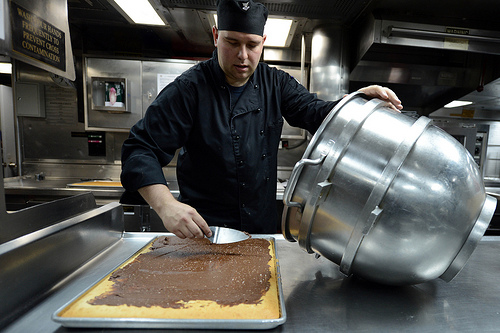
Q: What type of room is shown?
A: It is a kitchen.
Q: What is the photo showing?
A: It is showing a kitchen.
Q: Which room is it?
A: It is a kitchen.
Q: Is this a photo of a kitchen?
A: Yes, it is showing a kitchen.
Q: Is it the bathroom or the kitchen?
A: It is the kitchen.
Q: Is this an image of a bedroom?
A: No, the picture is showing a kitchen.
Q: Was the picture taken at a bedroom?
A: No, the picture was taken in a kitchen.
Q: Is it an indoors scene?
A: Yes, it is indoors.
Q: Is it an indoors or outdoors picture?
A: It is indoors.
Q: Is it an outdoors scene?
A: No, it is indoors.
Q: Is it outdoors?
A: No, it is indoors.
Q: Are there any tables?
A: Yes, there is a table.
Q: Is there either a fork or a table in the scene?
A: Yes, there is a table.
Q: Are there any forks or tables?
A: Yes, there is a table.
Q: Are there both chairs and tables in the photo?
A: No, there is a table but no chairs.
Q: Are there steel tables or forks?
A: Yes, there is a steel table.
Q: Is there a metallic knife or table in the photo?
A: Yes, there is a metal table.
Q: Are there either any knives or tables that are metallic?
A: Yes, the table is metallic.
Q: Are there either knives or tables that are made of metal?
A: Yes, the table is made of metal.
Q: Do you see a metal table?
A: Yes, there is a metal table.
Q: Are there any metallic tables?
A: Yes, there is a metal table.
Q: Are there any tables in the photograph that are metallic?
A: Yes, there is a table that is metallic.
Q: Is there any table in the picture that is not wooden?
A: Yes, there is a metallic table.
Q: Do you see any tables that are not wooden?
A: Yes, there is a metallic table.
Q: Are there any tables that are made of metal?
A: Yes, there is a table that is made of metal.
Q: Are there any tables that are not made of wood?
A: Yes, there is a table that is made of metal.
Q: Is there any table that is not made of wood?
A: Yes, there is a table that is made of metal.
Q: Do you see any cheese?
A: No, there is no cheese.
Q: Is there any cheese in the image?
A: No, there is no cheese.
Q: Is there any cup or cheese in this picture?
A: No, there are no cheese or cups.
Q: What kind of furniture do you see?
A: The furniture is a table.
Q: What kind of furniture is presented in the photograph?
A: The furniture is a table.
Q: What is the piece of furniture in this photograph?
A: The piece of furniture is a table.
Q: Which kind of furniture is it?
A: The piece of furniture is a table.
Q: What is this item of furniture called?
A: This is a table.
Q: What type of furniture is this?
A: This is a table.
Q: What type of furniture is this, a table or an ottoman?
A: This is a table.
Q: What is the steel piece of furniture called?
A: The piece of furniture is a table.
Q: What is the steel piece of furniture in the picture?
A: The piece of furniture is a table.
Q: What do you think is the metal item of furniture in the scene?
A: The piece of furniture is a table.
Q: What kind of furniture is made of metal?
A: The furniture is a table.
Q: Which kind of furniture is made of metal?
A: The furniture is a table.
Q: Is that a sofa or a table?
A: That is a table.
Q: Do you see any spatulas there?
A: Yes, there is a spatula.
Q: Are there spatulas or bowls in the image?
A: Yes, there is a spatula.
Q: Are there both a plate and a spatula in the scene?
A: No, there is a spatula but no plates.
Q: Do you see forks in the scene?
A: No, there are no forks.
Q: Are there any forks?
A: No, there are no forks.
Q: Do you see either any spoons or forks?
A: No, there are no forks or spoons.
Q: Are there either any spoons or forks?
A: No, there are no forks or spoons.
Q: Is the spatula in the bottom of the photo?
A: Yes, the spatula is in the bottom of the image.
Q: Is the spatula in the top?
A: No, the spatula is in the bottom of the image.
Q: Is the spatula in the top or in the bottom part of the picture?
A: The spatula is in the bottom of the image.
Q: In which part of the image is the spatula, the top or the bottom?
A: The spatula is in the bottom of the image.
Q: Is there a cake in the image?
A: Yes, there is a cake.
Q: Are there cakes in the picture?
A: Yes, there is a cake.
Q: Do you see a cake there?
A: Yes, there is a cake.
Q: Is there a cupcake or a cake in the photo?
A: Yes, there is a cake.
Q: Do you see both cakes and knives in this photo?
A: No, there is a cake but no knives.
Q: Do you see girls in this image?
A: No, there are no girls.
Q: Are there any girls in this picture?
A: No, there are no girls.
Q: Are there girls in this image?
A: No, there are no girls.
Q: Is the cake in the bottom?
A: Yes, the cake is in the bottom of the image.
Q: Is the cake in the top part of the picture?
A: No, the cake is in the bottom of the image.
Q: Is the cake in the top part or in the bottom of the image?
A: The cake is in the bottom of the image.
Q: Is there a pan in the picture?
A: Yes, there is a pan.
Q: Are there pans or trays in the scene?
A: Yes, there is a pan.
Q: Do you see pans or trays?
A: Yes, there is a pan.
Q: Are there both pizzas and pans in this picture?
A: No, there is a pan but no pizzas.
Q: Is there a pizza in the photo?
A: No, there are no pizzas.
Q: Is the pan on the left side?
A: Yes, the pan is on the left of the image.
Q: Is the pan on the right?
A: No, the pan is on the left of the image.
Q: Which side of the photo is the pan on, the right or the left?
A: The pan is on the left of the image.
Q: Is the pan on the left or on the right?
A: The pan is on the left of the image.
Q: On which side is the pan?
A: The pan is on the left of the image.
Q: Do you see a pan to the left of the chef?
A: Yes, there is a pan to the left of the chef.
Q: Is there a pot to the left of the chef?
A: No, there is a pan to the left of the chef.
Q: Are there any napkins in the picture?
A: No, there are no napkins.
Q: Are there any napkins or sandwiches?
A: No, there are no napkins or sandwiches.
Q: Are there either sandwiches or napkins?
A: No, there are no napkins or sandwiches.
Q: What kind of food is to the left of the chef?
A: The food is a dessert.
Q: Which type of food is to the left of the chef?
A: The food is a dessert.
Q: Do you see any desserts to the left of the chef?
A: Yes, there is a dessert to the left of the chef.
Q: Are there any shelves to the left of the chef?
A: No, there is a dessert to the left of the chef.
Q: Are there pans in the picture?
A: Yes, there is a pan.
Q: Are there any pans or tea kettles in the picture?
A: Yes, there is a pan.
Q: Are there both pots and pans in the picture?
A: No, there is a pan but no pots.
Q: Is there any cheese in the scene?
A: No, there is no cheese.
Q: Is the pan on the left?
A: Yes, the pan is on the left of the image.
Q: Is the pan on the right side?
A: No, the pan is on the left of the image.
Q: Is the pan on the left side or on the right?
A: The pan is on the left of the image.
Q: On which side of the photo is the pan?
A: The pan is on the left of the image.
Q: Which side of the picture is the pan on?
A: The pan is on the left of the image.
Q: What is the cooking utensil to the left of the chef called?
A: The cooking utensil is a pan.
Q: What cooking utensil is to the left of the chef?
A: The cooking utensil is a pan.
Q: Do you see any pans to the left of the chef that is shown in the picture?
A: Yes, there is a pan to the left of the chef.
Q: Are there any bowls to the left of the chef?
A: No, there is a pan to the left of the chef.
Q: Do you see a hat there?
A: Yes, there is a hat.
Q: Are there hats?
A: Yes, there is a hat.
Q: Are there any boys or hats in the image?
A: Yes, there is a hat.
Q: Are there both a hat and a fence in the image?
A: No, there is a hat but no fences.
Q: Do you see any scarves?
A: No, there are no scarves.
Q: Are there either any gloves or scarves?
A: No, there are no scarves or gloves.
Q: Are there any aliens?
A: No, there are no aliens.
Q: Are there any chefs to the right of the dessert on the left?
A: Yes, there is a chef to the right of the dessert.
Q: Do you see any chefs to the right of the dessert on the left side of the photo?
A: Yes, there is a chef to the right of the dessert.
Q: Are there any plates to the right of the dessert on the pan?
A: No, there is a chef to the right of the dessert.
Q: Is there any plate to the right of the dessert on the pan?
A: No, there is a chef to the right of the dessert.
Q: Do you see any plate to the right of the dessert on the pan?
A: No, there is a chef to the right of the dessert.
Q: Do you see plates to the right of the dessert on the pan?
A: No, there is a chef to the right of the dessert.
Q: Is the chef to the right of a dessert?
A: Yes, the chef is to the right of a dessert.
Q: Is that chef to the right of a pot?
A: No, the chef is to the right of a dessert.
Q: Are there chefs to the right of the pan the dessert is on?
A: Yes, there is a chef to the right of the pan.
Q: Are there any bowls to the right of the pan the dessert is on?
A: No, there is a chef to the right of the pan.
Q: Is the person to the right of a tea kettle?
A: No, the chef is to the right of a pan.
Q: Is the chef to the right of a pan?
A: Yes, the chef is to the right of a pan.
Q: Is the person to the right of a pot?
A: No, the chef is to the right of a pan.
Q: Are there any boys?
A: No, there are no boys.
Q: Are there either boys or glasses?
A: No, there are no boys or glasses.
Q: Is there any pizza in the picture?
A: No, there are no pizzas.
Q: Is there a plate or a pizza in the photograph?
A: No, there are no pizzas or plates.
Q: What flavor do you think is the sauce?
A: This is a chocolate sauce.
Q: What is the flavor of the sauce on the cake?
A: This is a chocolate sauce.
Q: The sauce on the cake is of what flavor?
A: This is a chocolate sauce.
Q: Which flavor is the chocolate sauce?
A: This is a chocolate sauce.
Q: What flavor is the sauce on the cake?
A: This is a chocolate sauce.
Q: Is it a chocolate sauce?
A: Yes, this is a chocolate sauce.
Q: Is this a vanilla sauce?
A: No, this is a chocolate sauce.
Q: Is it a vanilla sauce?
A: No, this is a chocolate sauce.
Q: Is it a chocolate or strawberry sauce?
A: This is a chocolate sauce.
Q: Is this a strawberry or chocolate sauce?
A: This is a chocolate sauce.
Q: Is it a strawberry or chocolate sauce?
A: This is a chocolate sauce.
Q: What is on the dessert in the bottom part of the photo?
A: The sauce is on the cake.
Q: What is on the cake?
A: The sauce is on the cake.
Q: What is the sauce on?
A: The sauce is on the cake.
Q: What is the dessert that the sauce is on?
A: The dessert is a cake.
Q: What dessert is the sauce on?
A: The sauce is on the cake.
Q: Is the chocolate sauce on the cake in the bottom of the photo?
A: Yes, the sauce is on the cake.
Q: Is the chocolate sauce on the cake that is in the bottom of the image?
A: Yes, the sauce is on the cake.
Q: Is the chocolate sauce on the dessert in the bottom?
A: Yes, the sauce is on the cake.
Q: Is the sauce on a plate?
A: No, the sauce is on the cake.